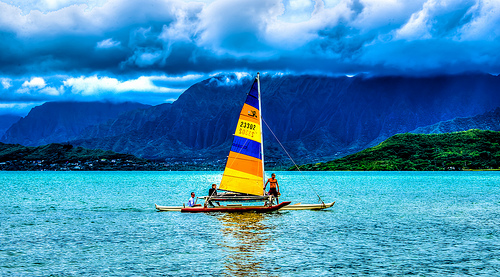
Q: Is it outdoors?
A: Yes, it is outdoors.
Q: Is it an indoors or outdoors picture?
A: It is outdoors.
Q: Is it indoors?
A: No, it is outdoors.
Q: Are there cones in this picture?
A: No, there are no cones.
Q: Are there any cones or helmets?
A: No, there are no cones or helmets.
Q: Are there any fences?
A: No, there are no fences.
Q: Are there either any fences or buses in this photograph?
A: No, there are no fences or buses.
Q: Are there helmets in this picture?
A: No, there are no helmets.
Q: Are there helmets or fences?
A: No, there are no helmets or fences.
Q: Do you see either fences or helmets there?
A: No, there are no helmets or fences.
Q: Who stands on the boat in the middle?
A: The man stands on the boat.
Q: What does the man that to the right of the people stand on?
A: The man stands on the boat.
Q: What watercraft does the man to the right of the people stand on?
A: The man stands on the boat.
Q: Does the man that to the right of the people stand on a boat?
A: Yes, the man stands on a boat.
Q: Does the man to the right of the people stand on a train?
A: No, the man stands on a boat.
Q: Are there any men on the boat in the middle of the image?
A: Yes, there is a man on the boat.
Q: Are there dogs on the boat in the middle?
A: No, there is a man on the boat.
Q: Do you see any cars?
A: No, there are no cars.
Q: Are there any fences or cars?
A: No, there are no cars or fences.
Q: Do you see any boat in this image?
A: Yes, there is a boat.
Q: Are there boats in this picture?
A: Yes, there is a boat.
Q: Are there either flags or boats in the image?
A: Yes, there is a boat.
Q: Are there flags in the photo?
A: No, there are no flags.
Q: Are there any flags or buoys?
A: No, there are no flags or buoys.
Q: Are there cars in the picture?
A: No, there are no cars.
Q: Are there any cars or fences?
A: No, there are no cars or fences.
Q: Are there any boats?
A: Yes, there is a boat.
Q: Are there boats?
A: Yes, there is a boat.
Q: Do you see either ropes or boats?
A: Yes, there is a boat.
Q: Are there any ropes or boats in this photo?
A: Yes, there is a boat.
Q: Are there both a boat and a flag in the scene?
A: No, there is a boat but no flags.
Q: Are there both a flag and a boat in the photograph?
A: No, there is a boat but no flags.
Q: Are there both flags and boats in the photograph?
A: No, there is a boat but no flags.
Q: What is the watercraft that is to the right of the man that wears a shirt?
A: The watercraft is a boat.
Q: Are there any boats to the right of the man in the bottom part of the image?
A: Yes, there is a boat to the right of the man.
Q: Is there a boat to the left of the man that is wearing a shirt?
A: No, the boat is to the right of the man.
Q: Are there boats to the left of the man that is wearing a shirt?
A: No, the boat is to the right of the man.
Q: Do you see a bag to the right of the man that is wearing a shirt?
A: No, there is a boat to the right of the man.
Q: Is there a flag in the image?
A: No, there are no flags.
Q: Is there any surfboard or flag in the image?
A: No, there are no flags or surfboards.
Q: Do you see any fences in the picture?
A: No, there are no fences.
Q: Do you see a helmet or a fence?
A: No, there are no fences or helmets.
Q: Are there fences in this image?
A: No, there are no fences.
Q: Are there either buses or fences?
A: No, there are no fences or buses.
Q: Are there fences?
A: No, there are no fences.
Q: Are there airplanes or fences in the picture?
A: No, there are no fences or airplanes.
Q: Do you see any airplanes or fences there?
A: No, there are no fences or airplanes.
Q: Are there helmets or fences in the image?
A: No, there are no fences or helmets.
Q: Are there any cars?
A: No, there are no cars.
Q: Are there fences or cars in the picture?
A: No, there are no cars or fences.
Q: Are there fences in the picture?
A: No, there are no fences.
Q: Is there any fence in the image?
A: No, there are no fences.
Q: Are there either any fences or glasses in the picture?
A: No, there are no fences or glasses.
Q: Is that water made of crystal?
A: Yes, the water is made of crystal.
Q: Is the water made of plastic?
A: No, the water is made of crystal.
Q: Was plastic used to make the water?
A: No, the water is made of crystal.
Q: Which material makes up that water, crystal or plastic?
A: The water is made of crystal.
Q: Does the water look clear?
A: Yes, the water is clear.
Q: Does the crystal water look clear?
A: Yes, the water is clear.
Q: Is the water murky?
A: No, the water is clear.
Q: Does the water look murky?
A: No, the water is clear.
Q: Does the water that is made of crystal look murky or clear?
A: The water is clear.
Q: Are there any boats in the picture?
A: Yes, there is a boat.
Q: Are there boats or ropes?
A: Yes, there is a boat.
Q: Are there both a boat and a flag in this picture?
A: No, there is a boat but no flags.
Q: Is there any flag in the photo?
A: No, there are no flags.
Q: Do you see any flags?
A: No, there are no flags.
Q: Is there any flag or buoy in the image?
A: No, there are no flags or buoys.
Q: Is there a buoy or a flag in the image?
A: No, there are no flags or buoys.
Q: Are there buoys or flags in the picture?
A: No, there are no flags or buoys.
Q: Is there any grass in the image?
A: Yes, there is grass.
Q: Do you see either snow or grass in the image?
A: Yes, there is grass.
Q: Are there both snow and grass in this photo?
A: No, there is grass but no snow.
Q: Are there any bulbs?
A: No, there are no bulbs.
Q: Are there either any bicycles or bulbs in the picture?
A: No, there are no bulbs or bicycles.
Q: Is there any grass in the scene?
A: Yes, there is grass.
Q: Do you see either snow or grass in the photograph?
A: Yes, there is grass.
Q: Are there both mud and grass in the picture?
A: No, there is grass but no mud.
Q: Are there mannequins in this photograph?
A: No, there are no mannequins.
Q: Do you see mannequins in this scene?
A: No, there are no mannequins.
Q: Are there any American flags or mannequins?
A: No, there are no mannequins or American flags.